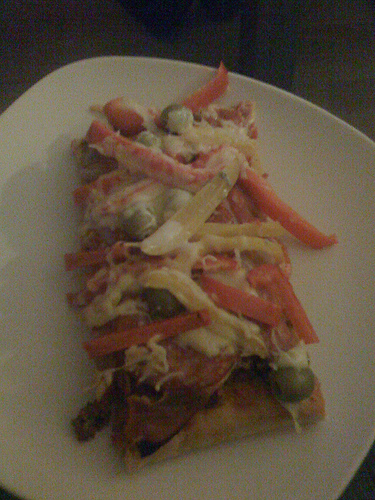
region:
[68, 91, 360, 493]
White plate with food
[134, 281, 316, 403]
Green peas on a food plate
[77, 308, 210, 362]
Orange carrot on a food topping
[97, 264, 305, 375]
Cheese garnish on a flat bread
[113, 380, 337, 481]
Flat bread with food topping on it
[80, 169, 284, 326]
Vegetable mixture as a food topping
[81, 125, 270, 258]
Thin sliced vegetables on top of bread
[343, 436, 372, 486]
Edge of white plate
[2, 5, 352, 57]
Black counter top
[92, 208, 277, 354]
Healthy vegetables as a snack topping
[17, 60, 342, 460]
Food on a plate.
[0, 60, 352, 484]
A square plate.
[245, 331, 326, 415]
A green olive.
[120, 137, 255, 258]
A piece of onion.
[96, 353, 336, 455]
Crust of deli sandwich.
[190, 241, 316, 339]
Slices of red peppers.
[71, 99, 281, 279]
White sauce on a deli type sanwich.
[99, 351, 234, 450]
Some meat on a sandwich.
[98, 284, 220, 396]
Shredded cheese on a sandwich.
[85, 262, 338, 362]
Three pieces of red peppers.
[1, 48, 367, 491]
a white plate with a gourmet piece of food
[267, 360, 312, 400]
a green olive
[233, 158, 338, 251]
sliced cooked sweet potato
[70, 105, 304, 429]
bread with meat, vegetables and cheese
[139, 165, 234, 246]
a sliced cooked potato covered in cheese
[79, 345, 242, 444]
cooked lunch meat with burnt edges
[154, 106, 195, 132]
olive covered in cheese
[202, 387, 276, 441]
cooked bread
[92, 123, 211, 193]
sweet potato covered in cheese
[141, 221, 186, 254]
melted cooked cheese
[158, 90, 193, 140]
A pea covered in sauce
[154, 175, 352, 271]
Strips of red and yellow bell pepper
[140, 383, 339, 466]
A tasty appetizer on a cracker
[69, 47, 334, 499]
A delicious vegetable loaded appetizer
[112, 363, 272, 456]
Crisp bacon served on cracker.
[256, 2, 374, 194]
A white food platter for serving appetizers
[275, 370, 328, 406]
A whole green olive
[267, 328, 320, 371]
White melted cheese on cracker.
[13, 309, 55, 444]
White platter for serving food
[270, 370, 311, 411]
A green olive on the edge of the crust below.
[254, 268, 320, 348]
A slice of red pepper.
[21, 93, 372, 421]
Dish with food prepared on it.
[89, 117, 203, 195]
Sauce on vegetable slice.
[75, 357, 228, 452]
Bacon slices, extending past crust.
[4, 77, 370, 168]
Top of oval, white serving platter.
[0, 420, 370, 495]
Bottom of oval, white serving platter.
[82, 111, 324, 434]
Creamy dish with vegetables and meat, on grain food item.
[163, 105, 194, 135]
Olive doused in sauce.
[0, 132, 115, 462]
Shadow on plate.